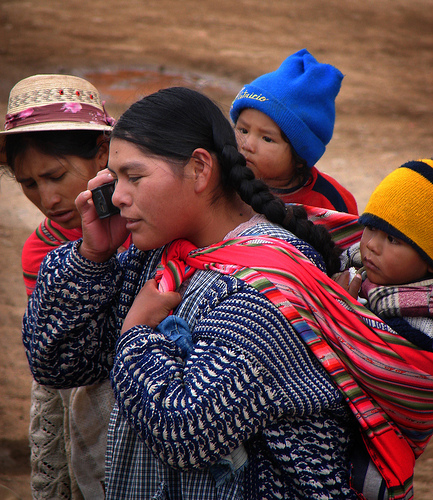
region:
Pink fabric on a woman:
[150, 231, 383, 419]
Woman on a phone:
[55, 86, 310, 268]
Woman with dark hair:
[60, 87, 363, 277]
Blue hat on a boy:
[214, 33, 384, 202]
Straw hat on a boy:
[0, 73, 147, 160]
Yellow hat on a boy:
[351, 146, 432, 267]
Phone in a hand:
[72, 166, 162, 243]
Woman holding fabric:
[105, 278, 198, 367]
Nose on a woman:
[93, 184, 149, 219]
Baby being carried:
[286, 140, 430, 273]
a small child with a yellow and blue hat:
[349, 130, 430, 282]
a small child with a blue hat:
[206, 25, 371, 191]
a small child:
[205, 28, 368, 239]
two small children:
[214, 53, 429, 308]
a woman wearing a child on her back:
[56, 66, 430, 370]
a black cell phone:
[78, 174, 147, 248]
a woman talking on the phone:
[57, 60, 298, 300]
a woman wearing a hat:
[9, 45, 140, 229]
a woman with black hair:
[84, 89, 283, 291]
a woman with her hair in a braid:
[83, 60, 378, 311]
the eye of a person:
[127, 170, 151, 193]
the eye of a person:
[260, 131, 277, 148]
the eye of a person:
[235, 122, 249, 136]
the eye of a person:
[383, 231, 400, 248]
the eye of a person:
[362, 222, 376, 238]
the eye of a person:
[46, 171, 67, 184]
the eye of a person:
[21, 176, 37, 193]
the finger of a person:
[75, 190, 99, 219]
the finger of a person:
[86, 169, 114, 182]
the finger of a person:
[166, 292, 179, 304]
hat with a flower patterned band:
[0, 75, 115, 130]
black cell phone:
[89, 180, 120, 218]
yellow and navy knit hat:
[359, 157, 431, 261]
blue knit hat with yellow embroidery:
[230, 48, 344, 166]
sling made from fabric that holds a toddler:
[153, 204, 430, 495]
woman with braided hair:
[21, 87, 359, 497]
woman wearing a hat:
[0, 76, 137, 296]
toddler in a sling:
[328, 157, 430, 497]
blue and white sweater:
[21, 226, 353, 498]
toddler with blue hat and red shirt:
[230, 49, 358, 215]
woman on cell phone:
[42, 91, 406, 498]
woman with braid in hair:
[111, 68, 346, 272]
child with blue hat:
[227, 30, 358, 206]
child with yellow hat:
[364, 132, 430, 273]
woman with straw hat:
[6, 59, 134, 211]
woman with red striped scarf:
[118, 92, 401, 476]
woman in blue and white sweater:
[81, 63, 327, 484]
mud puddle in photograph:
[68, 35, 268, 122]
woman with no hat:
[90, 75, 289, 297]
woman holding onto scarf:
[69, 84, 349, 337]